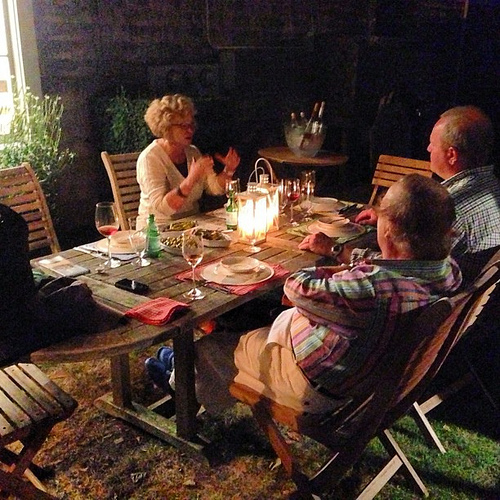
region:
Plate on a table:
[204, 253, 273, 283]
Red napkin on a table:
[127, 295, 184, 321]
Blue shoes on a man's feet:
[142, 348, 179, 384]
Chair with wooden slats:
[3, 160, 67, 250]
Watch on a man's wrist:
[325, 239, 343, 257]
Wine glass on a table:
[178, 231, 207, 300]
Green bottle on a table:
[144, 213, 164, 258]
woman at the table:
[133, 88, 244, 224]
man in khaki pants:
[140, 173, 466, 435]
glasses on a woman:
[168, 118, 195, 130]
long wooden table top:
[6, 188, 391, 356]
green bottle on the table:
[144, 213, 164, 263]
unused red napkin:
[119, 295, 189, 326]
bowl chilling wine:
[280, 115, 326, 162]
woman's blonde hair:
[136, 93, 196, 135]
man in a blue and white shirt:
[356, 109, 498, 271]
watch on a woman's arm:
[171, 183, 189, 204]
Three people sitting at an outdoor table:
[134, 102, 498, 497]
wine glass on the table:
[94, 197, 119, 266]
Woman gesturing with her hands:
[137, 91, 244, 216]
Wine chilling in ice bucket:
[283, 100, 326, 155]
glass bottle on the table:
[145, 211, 160, 263]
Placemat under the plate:
[180, 251, 287, 296]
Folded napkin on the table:
[128, 293, 188, 329]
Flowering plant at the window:
[0, 77, 77, 201]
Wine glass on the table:
[179, 228, 205, 305]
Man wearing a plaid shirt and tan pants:
[150, 172, 464, 430]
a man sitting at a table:
[175, 158, 456, 490]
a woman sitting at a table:
[108, 85, 245, 241]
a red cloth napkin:
[135, 288, 187, 332]